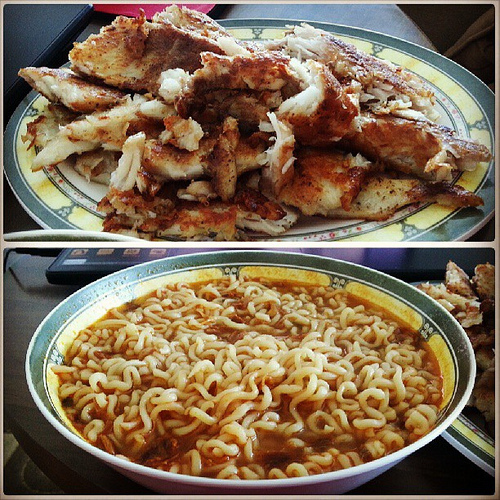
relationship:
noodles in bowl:
[71, 263, 406, 488] [16, 244, 482, 498]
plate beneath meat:
[2, 16, 492, 253] [27, 10, 480, 233]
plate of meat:
[407, 274, 494, 478] [435, 274, 497, 429]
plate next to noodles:
[407, 274, 494, 478] [65, 268, 430, 475]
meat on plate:
[90, 5, 380, 193] [29, 35, 476, 250]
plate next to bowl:
[409, 280, 500, 478] [16, 244, 482, 498]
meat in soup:
[248, 418, 295, 466] [46, 266, 488, 489]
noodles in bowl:
[213, 351, 310, 368] [16, 244, 482, 498]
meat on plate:
[46, 10, 461, 217] [2, 16, 492, 253]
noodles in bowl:
[181, 286, 373, 390] [16, 244, 482, 498]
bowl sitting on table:
[16, 244, 482, 498] [6, 250, 484, 497]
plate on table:
[2, 16, 492, 253] [364, 11, 411, 31]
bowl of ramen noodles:
[16, 244, 482, 498] [50, 273, 445, 480]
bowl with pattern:
[16, 244, 482, 498] [27, 248, 475, 486]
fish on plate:
[93, 37, 408, 207] [16, 167, 87, 234]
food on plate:
[18, 5, 490, 239] [2, 21, 475, 252]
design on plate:
[17, 163, 103, 230] [2, 21, 475, 252]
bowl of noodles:
[16, 244, 482, 498] [199, 295, 355, 397]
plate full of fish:
[2, 21, 475, 252] [40, 29, 432, 224]